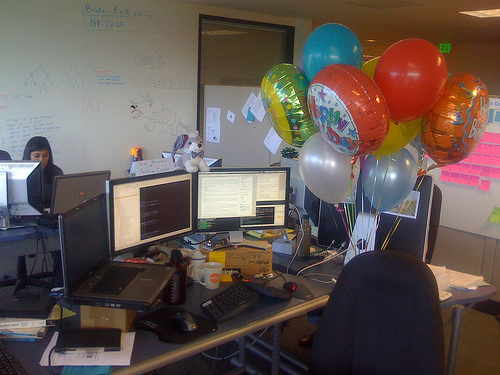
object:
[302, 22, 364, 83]
balloons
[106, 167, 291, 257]
monitors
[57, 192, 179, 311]
laptop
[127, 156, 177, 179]
card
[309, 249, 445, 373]
chair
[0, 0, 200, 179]
board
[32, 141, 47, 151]
hair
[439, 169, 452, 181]
notes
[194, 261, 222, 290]
mug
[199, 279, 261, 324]
keyboard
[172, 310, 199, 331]
mouse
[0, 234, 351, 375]
desk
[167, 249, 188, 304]
bottle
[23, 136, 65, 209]
woman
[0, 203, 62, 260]
desk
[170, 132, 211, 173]
animal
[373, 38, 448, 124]
balloon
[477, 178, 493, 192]
note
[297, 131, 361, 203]
balloon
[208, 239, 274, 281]
box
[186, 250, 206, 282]
cup